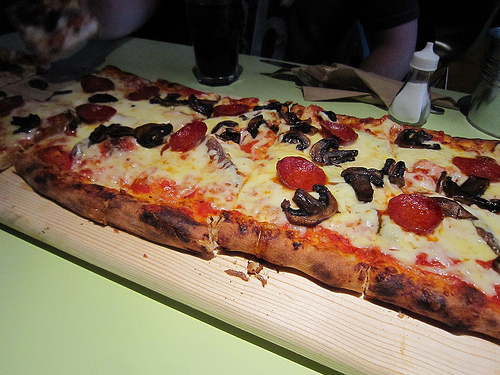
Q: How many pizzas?
A: One.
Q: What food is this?
A: Pizza.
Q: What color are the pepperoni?
A: Red.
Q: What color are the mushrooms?
A: Brown.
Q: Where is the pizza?
A: On the table.